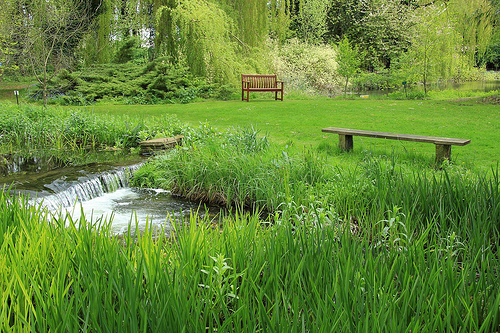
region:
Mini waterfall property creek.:
[17, 149, 250, 255]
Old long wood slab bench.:
[311, 118, 472, 165]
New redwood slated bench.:
[236, 66, 288, 106]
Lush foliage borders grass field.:
[69, 5, 236, 118]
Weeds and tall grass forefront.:
[210, 199, 477, 329]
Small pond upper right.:
[369, 78, 495, 99]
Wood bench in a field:
[319, 112, 469, 160]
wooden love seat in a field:
[238, 70, 293, 115]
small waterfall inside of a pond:
[34, 160, 136, 219]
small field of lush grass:
[288, 99, 462, 128]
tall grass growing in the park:
[98, 229, 462, 330]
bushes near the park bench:
[55, 56, 232, 103]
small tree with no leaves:
[18, 15, 73, 96]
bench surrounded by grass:
[326, 111, 477, 168]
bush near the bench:
[273, 39, 334, 82]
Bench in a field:
[239, 67, 290, 107]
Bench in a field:
[319, 113, 477, 176]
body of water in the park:
[45, 166, 134, 218]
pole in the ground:
[9, 85, 23, 110]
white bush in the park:
[259, 30, 350, 92]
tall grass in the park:
[106, 206, 498, 331]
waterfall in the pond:
[28, 166, 131, 221]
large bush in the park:
[8, 13, 221, 122]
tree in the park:
[408, 1, 493, 66]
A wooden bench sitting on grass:
[240, 72, 285, 99]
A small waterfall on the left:
[27, 156, 163, 201]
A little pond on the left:
[0, 150, 247, 230]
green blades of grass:
[2, 200, 494, 327]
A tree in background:
[20, 10, 95, 105]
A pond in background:
[415, 75, 495, 90]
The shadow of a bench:
[315, 140, 450, 160]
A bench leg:
[435, 140, 450, 161]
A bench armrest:
[240, 77, 247, 87]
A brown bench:
[240, 71, 283, 98]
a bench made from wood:
[240, 72, 285, 104]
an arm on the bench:
[238, 69, 252, 107]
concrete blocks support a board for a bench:
[320, 124, 469, 161]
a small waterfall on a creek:
[21, 155, 131, 222]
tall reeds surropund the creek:
[0, 188, 489, 330]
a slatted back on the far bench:
[243, 72, 280, 89]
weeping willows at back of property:
[145, 0, 285, 75]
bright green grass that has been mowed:
[93, 92, 498, 164]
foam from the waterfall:
[41, 181, 148, 227]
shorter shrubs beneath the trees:
[17, 58, 217, 99]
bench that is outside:
[326, 104, 486, 202]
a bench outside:
[240, 62, 296, 149]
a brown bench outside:
[219, 63, 314, 115]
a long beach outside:
[315, 115, 481, 204]